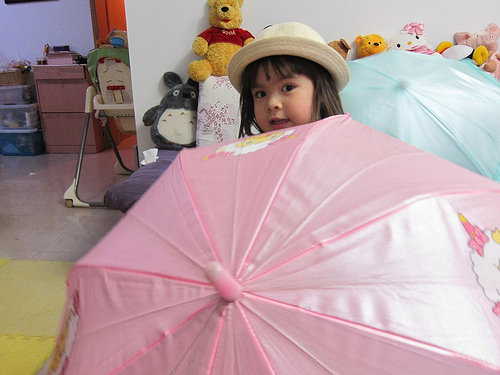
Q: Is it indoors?
A: Yes, it is indoors.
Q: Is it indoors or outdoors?
A: It is indoors.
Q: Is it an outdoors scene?
A: No, it is indoors.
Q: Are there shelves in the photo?
A: No, there are no shelves.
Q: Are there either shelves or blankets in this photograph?
A: No, there are no shelves or blankets.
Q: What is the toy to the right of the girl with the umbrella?
A: The toy is a stuffed animal.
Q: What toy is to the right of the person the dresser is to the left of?
A: The toy is a stuffed animal.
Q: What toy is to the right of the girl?
A: The toy is a stuffed animal.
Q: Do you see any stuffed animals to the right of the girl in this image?
A: Yes, there is a stuffed animal to the right of the girl.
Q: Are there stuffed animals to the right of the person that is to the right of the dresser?
A: Yes, there is a stuffed animal to the right of the girl.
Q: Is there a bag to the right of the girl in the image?
A: No, there is a stuffed animal to the right of the girl.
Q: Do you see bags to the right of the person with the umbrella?
A: No, there is a stuffed animal to the right of the girl.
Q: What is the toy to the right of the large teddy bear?
A: The toy is a stuffed animal.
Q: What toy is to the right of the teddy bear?
A: The toy is a stuffed animal.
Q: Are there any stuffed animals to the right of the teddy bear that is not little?
A: Yes, there is a stuffed animal to the right of the teddy bear.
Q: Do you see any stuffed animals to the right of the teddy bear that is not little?
A: Yes, there is a stuffed animal to the right of the teddy bear.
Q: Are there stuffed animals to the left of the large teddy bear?
A: No, the stuffed animal is to the right of the teddy bear.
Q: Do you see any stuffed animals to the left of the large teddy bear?
A: No, the stuffed animal is to the right of the teddy bear.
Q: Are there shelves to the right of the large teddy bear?
A: No, there is a stuffed animal to the right of the teddy bear.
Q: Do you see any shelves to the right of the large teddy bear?
A: No, there is a stuffed animal to the right of the teddy bear.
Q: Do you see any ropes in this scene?
A: No, there are no ropes.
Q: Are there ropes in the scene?
A: No, there are no ropes.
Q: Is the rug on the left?
A: Yes, the rug is on the left of the image.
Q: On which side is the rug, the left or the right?
A: The rug is on the left of the image.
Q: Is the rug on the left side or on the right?
A: The rug is on the left of the image.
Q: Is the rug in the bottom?
A: Yes, the rug is in the bottom of the image.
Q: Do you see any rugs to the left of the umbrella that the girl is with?
A: Yes, there is a rug to the left of the umbrella.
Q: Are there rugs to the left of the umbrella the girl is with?
A: Yes, there is a rug to the left of the umbrella.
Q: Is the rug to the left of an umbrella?
A: Yes, the rug is to the left of an umbrella.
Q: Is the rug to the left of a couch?
A: No, the rug is to the left of an umbrella.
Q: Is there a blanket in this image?
A: No, there are no blankets.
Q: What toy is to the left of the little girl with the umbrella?
A: The toy is a stuffed animal.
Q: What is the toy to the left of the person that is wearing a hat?
A: The toy is a stuffed animal.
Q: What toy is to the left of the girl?
A: The toy is a stuffed animal.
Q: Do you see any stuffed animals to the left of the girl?
A: Yes, there is a stuffed animal to the left of the girl.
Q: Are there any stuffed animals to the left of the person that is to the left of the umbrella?
A: Yes, there is a stuffed animal to the left of the girl.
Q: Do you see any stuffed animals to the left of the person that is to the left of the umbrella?
A: Yes, there is a stuffed animal to the left of the girl.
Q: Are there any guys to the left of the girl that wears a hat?
A: No, there is a stuffed animal to the left of the girl.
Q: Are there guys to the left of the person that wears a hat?
A: No, there is a stuffed animal to the left of the girl.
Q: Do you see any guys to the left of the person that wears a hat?
A: No, there is a stuffed animal to the left of the girl.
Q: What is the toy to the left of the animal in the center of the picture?
A: The toy is a stuffed animal.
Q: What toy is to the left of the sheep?
A: The toy is a stuffed animal.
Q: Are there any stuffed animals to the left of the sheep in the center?
A: Yes, there is a stuffed animal to the left of the sheep.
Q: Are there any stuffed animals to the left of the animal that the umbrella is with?
A: Yes, there is a stuffed animal to the left of the sheep.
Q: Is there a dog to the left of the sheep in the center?
A: No, there is a stuffed animal to the left of the sheep.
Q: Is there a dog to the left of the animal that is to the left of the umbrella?
A: No, there is a stuffed animal to the left of the sheep.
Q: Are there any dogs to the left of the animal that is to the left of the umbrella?
A: No, there is a stuffed animal to the left of the sheep.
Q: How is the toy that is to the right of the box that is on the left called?
A: The toy is a stuffed animal.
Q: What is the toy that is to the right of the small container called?
A: The toy is a stuffed animal.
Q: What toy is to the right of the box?
A: The toy is a stuffed animal.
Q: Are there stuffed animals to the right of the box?
A: Yes, there is a stuffed animal to the right of the box.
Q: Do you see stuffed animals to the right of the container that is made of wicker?
A: Yes, there is a stuffed animal to the right of the box.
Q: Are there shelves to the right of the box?
A: No, there is a stuffed animal to the right of the box.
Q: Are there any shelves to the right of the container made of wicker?
A: No, there is a stuffed animal to the right of the box.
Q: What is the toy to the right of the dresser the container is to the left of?
A: The toy is a stuffed animal.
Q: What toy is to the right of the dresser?
A: The toy is a stuffed animal.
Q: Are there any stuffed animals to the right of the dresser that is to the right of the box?
A: Yes, there is a stuffed animal to the right of the dresser.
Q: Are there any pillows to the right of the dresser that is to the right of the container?
A: No, there is a stuffed animal to the right of the dresser.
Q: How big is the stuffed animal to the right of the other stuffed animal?
A: The stuffed animal is large.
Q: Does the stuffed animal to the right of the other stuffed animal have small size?
A: No, the stuffed animal is large.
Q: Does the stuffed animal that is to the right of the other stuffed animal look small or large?
A: The stuffed animal is large.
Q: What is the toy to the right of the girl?
A: The toy is a stuffed animal.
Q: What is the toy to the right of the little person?
A: The toy is a stuffed animal.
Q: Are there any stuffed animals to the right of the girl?
A: Yes, there is a stuffed animal to the right of the girl.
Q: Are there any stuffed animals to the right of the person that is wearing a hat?
A: Yes, there is a stuffed animal to the right of the girl.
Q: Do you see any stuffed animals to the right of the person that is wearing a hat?
A: Yes, there is a stuffed animal to the right of the girl.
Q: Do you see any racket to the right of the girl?
A: No, there is a stuffed animal to the right of the girl.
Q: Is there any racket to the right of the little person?
A: No, there is a stuffed animal to the right of the girl.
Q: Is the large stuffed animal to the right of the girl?
A: Yes, the stuffed animal is to the right of the girl.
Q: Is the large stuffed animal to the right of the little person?
A: Yes, the stuffed animal is to the right of the girl.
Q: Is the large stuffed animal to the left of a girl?
A: No, the stuffed animal is to the right of a girl.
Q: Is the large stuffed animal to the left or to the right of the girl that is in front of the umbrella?
A: The stuffed animal is to the right of the girl.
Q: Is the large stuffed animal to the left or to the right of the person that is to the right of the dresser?
A: The stuffed animal is to the right of the girl.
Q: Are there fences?
A: No, there are no fences.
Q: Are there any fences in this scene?
A: No, there are no fences.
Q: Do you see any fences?
A: No, there are no fences.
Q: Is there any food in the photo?
A: No, there is no food.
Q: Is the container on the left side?
A: Yes, the container is on the left of the image.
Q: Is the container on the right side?
A: No, the container is on the left of the image.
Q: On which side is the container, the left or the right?
A: The container is on the left of the image.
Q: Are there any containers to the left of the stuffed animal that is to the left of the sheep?
A: Yes, there is a container to the left of the stuffed animal.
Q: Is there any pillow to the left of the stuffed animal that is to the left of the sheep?
A: No, there is a container to the left of the stuffed animal.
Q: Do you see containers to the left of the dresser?
A: Yes, there is a container to the left of the dresser.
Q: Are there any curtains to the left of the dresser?
A: No, there is a container to the left of the dresser.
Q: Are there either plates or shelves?
A: No, there are no shelves or plates.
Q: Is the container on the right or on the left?
A: The container is on the left of the image.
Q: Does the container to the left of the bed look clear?
A: Yes, the container is clear.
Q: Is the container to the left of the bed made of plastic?
A: Yes, the container is made of plastic.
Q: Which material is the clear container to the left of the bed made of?
A: The container is made of plastic.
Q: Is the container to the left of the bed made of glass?
A: No, the container is made of plastic.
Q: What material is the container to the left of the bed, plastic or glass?
A: The container is made of plastic.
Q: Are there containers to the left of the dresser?
A: Yes, there is a container to the left of the dresser.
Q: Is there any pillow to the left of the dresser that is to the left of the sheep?
A: No, there is a container to the left of the dresser.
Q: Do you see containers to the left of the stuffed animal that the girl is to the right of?
A: Yes, there is a container to the left of the stuffed animal.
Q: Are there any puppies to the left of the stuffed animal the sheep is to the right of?
A: No, there is a container to the left of the stuffed animal.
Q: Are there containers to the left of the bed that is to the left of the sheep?
A: Yes, there is a container to the left of the bed.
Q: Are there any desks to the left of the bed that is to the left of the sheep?
A: No, there is a container to the left of the bed.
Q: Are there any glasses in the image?
A: No, there are no glasses.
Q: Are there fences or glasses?
A: No, there are no glasses or fences.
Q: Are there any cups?
A: No, there are no cups.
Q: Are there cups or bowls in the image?
A: No, there are no cups or bowls.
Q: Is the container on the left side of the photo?
A: Yes, the container is on the left of the image.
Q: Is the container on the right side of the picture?
A: No, the container is on the left of the image.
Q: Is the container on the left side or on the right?
A: The container is on the left of the image.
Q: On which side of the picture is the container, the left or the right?
A: The container is on the left of the image.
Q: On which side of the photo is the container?
A: The container is on the left of the image.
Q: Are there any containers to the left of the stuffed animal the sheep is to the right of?
A: Yes, there is a container to the left of the stuffed animal.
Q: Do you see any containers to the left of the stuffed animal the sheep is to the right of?
A: Yes, there is a container to the left of the stuffed animal.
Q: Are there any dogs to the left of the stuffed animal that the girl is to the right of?
A: No, there is a container to the left of the stuffed animal.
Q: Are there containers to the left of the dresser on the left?
A: Yes, there is a container to the left of the dresser.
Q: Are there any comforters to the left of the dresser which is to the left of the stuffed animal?
A: No, there is a container to the left of the dresser.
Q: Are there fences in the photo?
A: No, there are no fences.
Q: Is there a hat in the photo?
A: Yes, there is a hat.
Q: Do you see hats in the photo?
A: Yes, there is a hat.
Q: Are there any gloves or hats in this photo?
A: Yes, there is a hat.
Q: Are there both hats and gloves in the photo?
A: No, there is a hat but no gloves.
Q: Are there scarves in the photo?
A: No, there are no scarves.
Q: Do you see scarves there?
A: No, there are no scarves.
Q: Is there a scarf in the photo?
A: No, there are no scarves.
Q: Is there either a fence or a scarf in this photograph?
A: No, there are no scarves or fences.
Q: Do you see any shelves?
A: No, there are no shelves.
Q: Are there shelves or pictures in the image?
A: No, there are no shelves or pictures.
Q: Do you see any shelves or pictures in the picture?
A: No, there are no shelves or pictures.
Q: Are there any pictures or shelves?
A: No, there are no shelves or pictures.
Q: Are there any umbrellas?
A: Yes, there is an umbrella.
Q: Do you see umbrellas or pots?
A: Yes, there is an umbrella.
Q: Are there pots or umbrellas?
A: Yes, there is an umbrella.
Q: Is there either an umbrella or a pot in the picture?
A: Yes, there is an umbrella.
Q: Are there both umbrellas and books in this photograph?
A: No, there is an umbrella but no books.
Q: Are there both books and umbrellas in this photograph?
A: No, there is an umbrella but no books.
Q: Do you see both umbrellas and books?
A: No, there is an umbrella but no books.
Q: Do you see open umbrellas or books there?
A: Yes, there is an open umbrella.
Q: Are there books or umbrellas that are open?
A: Yes, the umbrella is open.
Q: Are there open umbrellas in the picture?
A: Yes, there is an open umbrella.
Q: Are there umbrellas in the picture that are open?
A: Yes, there is an umbrella that is open.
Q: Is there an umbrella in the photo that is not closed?
A: Yes, there is a open umbrella.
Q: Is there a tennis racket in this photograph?
A: No, there are no rackets.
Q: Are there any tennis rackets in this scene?
A: No, there are no tennis rackets.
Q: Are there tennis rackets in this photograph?
A: No, there are no tennis rackets.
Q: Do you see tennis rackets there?
A: No, there are no tennis rackets.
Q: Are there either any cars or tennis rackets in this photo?
A: No, there are no tennis rackets or cars.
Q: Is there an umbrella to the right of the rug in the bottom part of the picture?
A: Yes, there is an umbrella to the right of the rug.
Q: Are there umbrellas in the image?
A: Yes, there is an umbrella.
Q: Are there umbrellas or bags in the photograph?
A: Yes, there is an umbrella.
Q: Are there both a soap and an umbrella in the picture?
A: No, there is an umbrella but no soaps.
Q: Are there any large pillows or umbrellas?
A: Yes, there is a large umbrella.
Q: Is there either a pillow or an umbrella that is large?
A: Yes, the umbrella is large.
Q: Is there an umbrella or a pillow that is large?
A: Yes, the umbrella is large.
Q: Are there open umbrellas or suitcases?
A: Yes, there is an open umbrella.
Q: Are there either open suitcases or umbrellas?
A: Yes, there is an open umbrella.